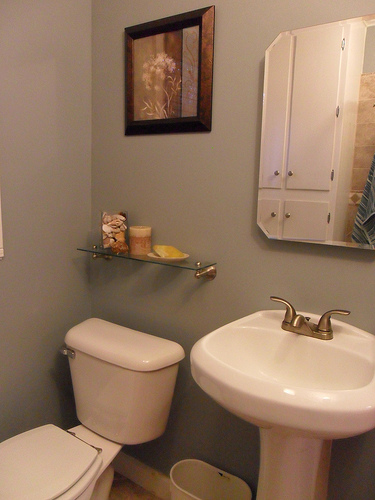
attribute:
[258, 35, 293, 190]
cabinet door — white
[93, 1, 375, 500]
wall — white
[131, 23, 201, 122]
picture — framed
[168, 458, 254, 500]
waste basket — plastic, white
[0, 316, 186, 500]
toilet — white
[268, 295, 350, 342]
faucet — stainless steel, bathroom faucet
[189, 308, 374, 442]
sink — porcelain, white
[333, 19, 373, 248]
mirror — vanity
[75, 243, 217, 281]
shelf — glass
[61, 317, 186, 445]
tank — porcelain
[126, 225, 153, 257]
candle — brown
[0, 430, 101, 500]
toilet bowl — porcelain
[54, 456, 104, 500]
toilet seat — plastic